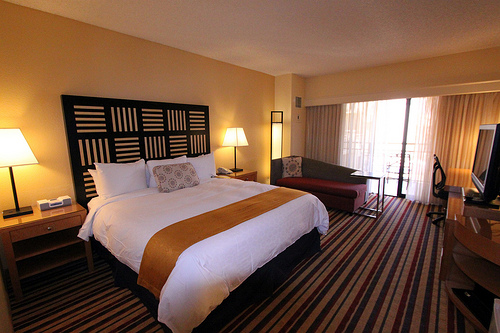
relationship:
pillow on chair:
[271, 147, 299, 180] [296, 179, 335, 204]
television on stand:
[457, 134, 494, 212] [444, 221, 484, 312]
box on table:
[28, 229, 70, 244] [12, 209, 84, 225]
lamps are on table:
[0, 163, 28, 212] [12, 209, 84, 225]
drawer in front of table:
[12, 228, 80, 234] [12, 209, 84, 225]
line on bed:
[190, 201, 223, 230] [97, 149, 323, 288]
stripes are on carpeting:
[62, 277, 101, 295] [303, 279, 347, 300]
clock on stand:
[31, 194, 68, 215] [444, 221, 484, 312]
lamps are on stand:
[0, 163, 28, 212] [444, 221, 484, 312]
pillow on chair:
[271, 147, 299, 180] [270, 173, 368, 214]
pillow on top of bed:
[271, 147, 299, 180] [97, 149, 323, 288]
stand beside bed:
[444, 221, 484, 312] [97, 149, 323, 288]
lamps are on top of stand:
[0, 163, 28, 212] [444, 221, 484, 312]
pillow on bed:
[271, 147, 299, 180] [97, 149, 323, 288]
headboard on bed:
[102, 106, 155, 164] [97, 149, 323, 288]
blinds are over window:
[280, 109, 321, 135] [326, 96, 402, 151]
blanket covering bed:
[155, 203, 186, 224] [97, 149, 323, 288]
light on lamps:
[1, 136, 18, 153] [0, 163, 28, 212]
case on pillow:
[133, 170, 142, 187] [271, 147, 299, 180]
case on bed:
[133, 170, 142, 187] [97, 149, 323, 288]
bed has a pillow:
[97, 149, 323, 288] [271, 147, 299, 180]